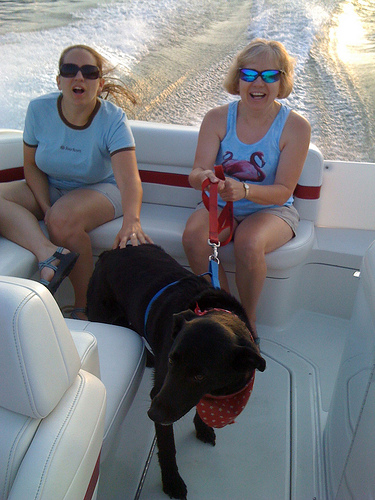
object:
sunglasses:
[240, 68, 282, 83]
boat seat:
[0, 199, 313, 276]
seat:
[61, 318, 145, 435]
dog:
[84, 242, 267, 499]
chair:
[0, 120, 323, 326]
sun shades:
[59, 63, 101, 81]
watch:
[243, 183, 250, 198]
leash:
[201, 165, 234, 246]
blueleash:
[209, 258, 220, 291]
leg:
[150, 374, 187, 499]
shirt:
[202, 102, 293, 215]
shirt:
[22, 90, 135, 188]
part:
[226, 409, 231, 414]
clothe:
[193, 307, 256, 429]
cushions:
[0, 121, 322, 500]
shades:
[240, 68, 277, 82]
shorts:
[196, 200, 301, 238]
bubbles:
[62, 5, 154, 46]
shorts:
[48, 181, 124, 219]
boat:
[0, 118, 375, 500]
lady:
[180, 41, 310, 346]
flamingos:
[219, 150, 266, 183]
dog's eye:
[169, 354, 207, 383]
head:
[147, 311, 266, 427]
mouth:
[147, 383, 204, 425]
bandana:
[198, 306, 256, 428]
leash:
[143, 260, 221, 351]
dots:
[198, 378, 255, 430]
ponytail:
[99, 77, 137, 107]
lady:
[0, 44, 154, 322]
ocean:
[0, 0, 374, 160]